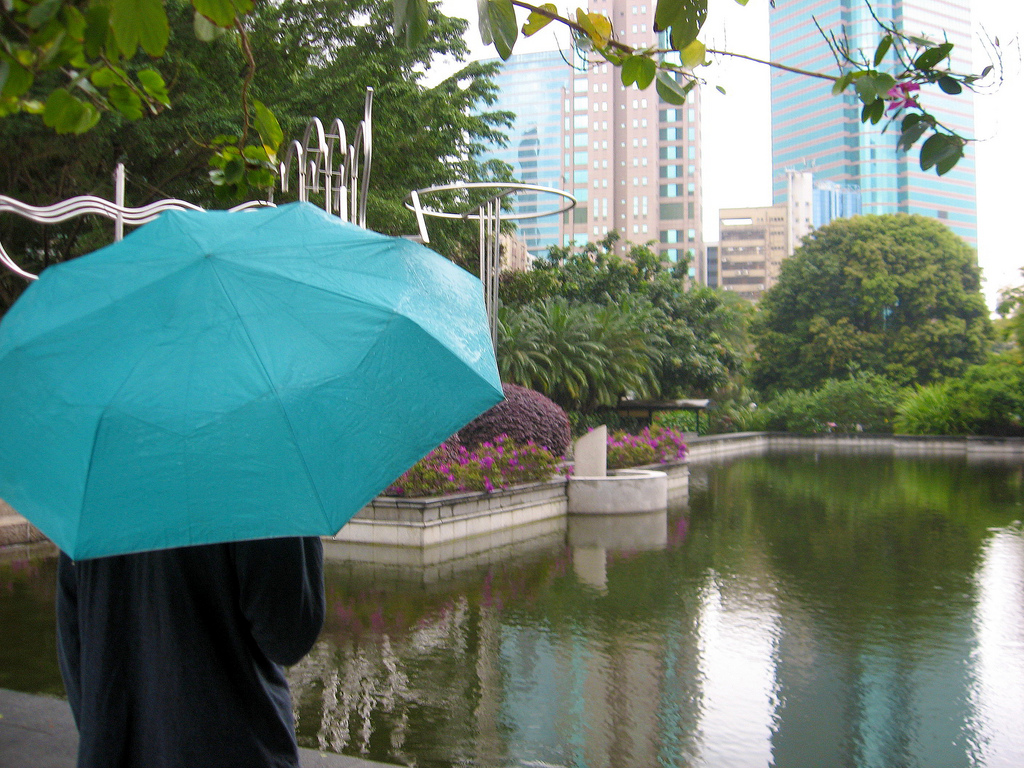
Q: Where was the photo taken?
A: A park.